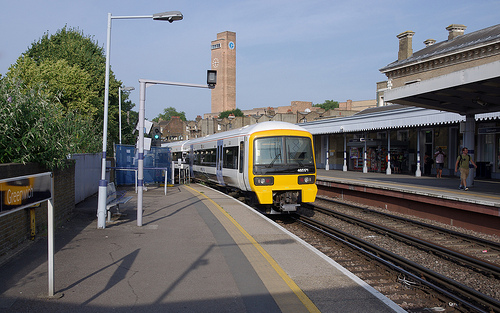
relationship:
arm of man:
[449, 154, 461, 176] [454, 146, 474, 188]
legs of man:
[457, 167, 469, 189] [453, 146, 477, 190]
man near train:
[453, 145, 481, 188] [148, 117, 324, 223]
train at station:
[148, 117, 324, 223] [33, 22, 496, 309]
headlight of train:
[300, 168, 317, 186] [159, 120, 317, 215]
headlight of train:
[252, 173, 266, 188] [159, 120, 317, 215]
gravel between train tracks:
[272, 192, 499, 311] [269, 192, 498, 312]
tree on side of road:
[31, 31, 98, 142] [143, 186, 209, 276]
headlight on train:
[254, 176, 273, 185] [206, 123, 337, 234]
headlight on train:
[299, 176, 315, 184] [206, 123, 337, 234]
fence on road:
[130, 142, 171, 197] [77, 186, 308, 311]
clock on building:
[210, 55, 221, 68] [210, 31, 237, 111]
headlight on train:
[299, 176, 315, 184] [159, 120, 317, 215]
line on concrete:
[182, 183, 319, 311] [0, 180, 405, 311]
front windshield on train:
[253, 132, 315, 172] [160, 118, 322, 220]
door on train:
[215, 139, 220, 181] [159, 120, 317, 215]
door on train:
[216, 140, 224, 185] [159, 120, 317, 215]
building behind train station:
[206, 28, 244, 110] [146, 128, 288, 298]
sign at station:
[1, 167, 63, 299] [333, 26, 496, 205]